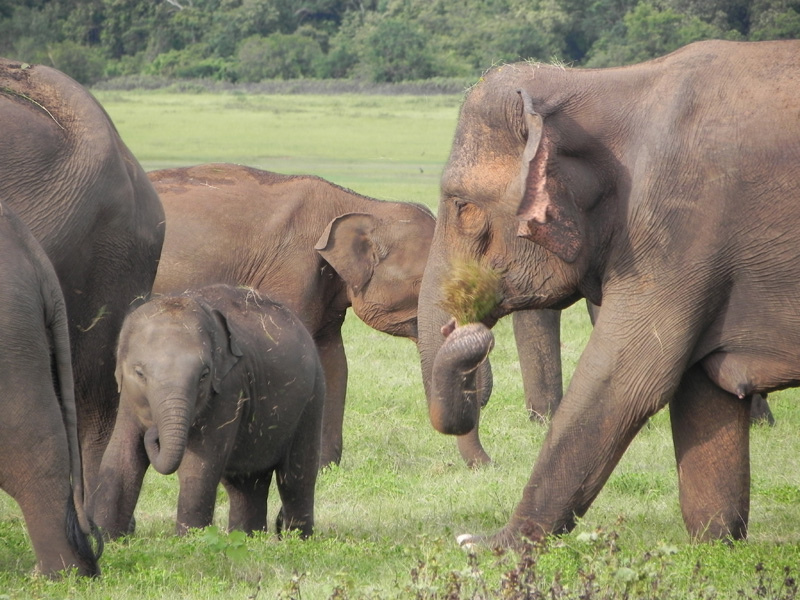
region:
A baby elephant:
[86, 286, 344, 544]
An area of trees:
[141, 17, 446, 76]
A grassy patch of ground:
[189, 538, 471, 596]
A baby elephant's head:
[112, 318, 224, 482]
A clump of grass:
[450, 247, 493, 330]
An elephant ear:
[307, 205, 387, 299]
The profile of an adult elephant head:
[377, 41, 607, 439]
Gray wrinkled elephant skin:
[656, 119, 789, 287]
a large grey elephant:
[409, 33, 796, 550]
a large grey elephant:
[144, 157, 485, 456]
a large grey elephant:
[5, 55, 161, 503]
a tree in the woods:
[591, 0, 739, 67]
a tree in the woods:
[341, 11, 440, 75]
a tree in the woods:
[437, 3, 567, 69]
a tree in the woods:
[97, 7, 198, 64]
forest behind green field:
[0, 0, 794, 216]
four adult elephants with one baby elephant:
[0, 40, 794, 568]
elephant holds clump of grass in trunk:
[410, 244, 492, 437]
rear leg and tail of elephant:
[0, 200, 104, 581]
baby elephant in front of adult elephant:
[92, 157, 434, 545]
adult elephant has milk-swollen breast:
[415, 38, 797, 555]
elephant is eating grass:
[412, 36, 798, 544]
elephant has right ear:
[147, 163, 437, 470]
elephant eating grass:
[401, 29, 798, 559]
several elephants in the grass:
[1, 18, 798, 588]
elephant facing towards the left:
[393, 21, 795, 566]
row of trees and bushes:
[0, 0, 790, 85]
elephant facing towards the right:
[89, 152, 518, 528]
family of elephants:
[3, 26, 790, 581]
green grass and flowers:
[132, 543, 716, 592]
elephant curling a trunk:
[405, 47, 633, 464]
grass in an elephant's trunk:
[419, 256, 529, 448]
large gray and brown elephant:
[419, 38, 798, 577]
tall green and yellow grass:
[132, 102, 182, 128]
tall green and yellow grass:
[362, 515, 403, 576]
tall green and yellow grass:
[630, 539, 667, 584]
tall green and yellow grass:
[228, 119, 293, 143]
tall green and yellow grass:
[145, 109, 195, 134]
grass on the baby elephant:
[240, 295, 285, 352]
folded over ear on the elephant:
[307, 213, 345, 267]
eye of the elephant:
[451, 189, 478, 214]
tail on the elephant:
[35, 253, 107, 567]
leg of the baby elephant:
[274, 469, 314, 543]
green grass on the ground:
[376, 480, 458, 529]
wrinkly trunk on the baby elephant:
[140, 417, 185, 476]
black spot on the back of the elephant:
[163, 162, 233, 198]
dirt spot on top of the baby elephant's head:
[153, 295, 191, 320]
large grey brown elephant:
[411, 36, 799, 562]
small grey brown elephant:
[76, 284, 328, 545]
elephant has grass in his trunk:
[434, 258, 518, 433]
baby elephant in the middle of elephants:
[86, 284, 324, 547]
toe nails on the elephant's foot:
[456, 530, 482, 558]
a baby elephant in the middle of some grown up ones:
[89, 282, 323, 540]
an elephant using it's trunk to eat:
[413, 39, 797, 561]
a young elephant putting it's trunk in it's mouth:
[88, 282, 325, 538]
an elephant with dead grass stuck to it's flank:
[96, 290, 324, 539]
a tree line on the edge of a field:
[5, 0, 798, 92]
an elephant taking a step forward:
[418, 37, 798, 549]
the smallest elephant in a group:
[88, 283, 324, 534]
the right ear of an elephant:
[316, 211, 385, 293]